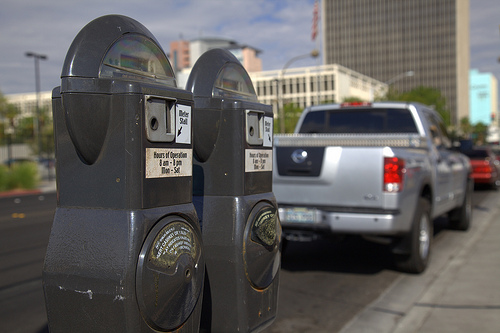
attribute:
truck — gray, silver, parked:
[276, 93, 481, 276]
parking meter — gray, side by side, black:
[34, 10, 289, 332]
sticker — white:
[140, 145, 195, 183]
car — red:
[462, 141, 499, 188]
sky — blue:
[8, 3, 308, 30]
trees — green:
[0, 93, 50, 191]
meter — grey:
[38, 7, 206, 333]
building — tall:
[321, 0, 477, 122]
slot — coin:
[161, 98, 176, 137]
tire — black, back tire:
[389, 195, 439, 281]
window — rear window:
[294, 105, 422, 136]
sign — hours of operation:
[143, 145, 193, 177]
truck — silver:
[271, 102, 472, 273]